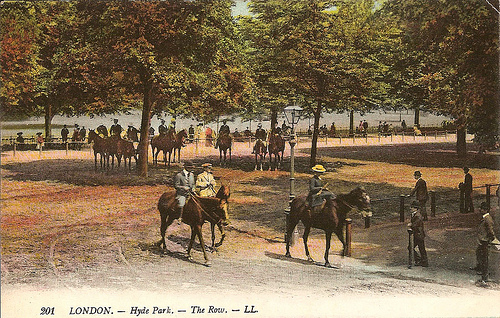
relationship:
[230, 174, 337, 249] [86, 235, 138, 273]
carriage has tracks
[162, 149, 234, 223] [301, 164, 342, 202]
woman in hat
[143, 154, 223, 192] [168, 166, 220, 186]
men in suits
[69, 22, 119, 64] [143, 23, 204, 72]
leaves on tree